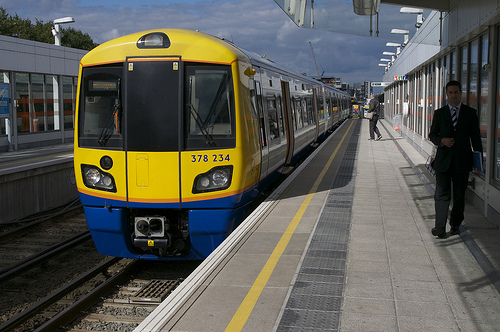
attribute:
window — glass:
[183, 66, 233, 138]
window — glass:
[90, 79, 122, 150]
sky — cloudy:
[80, 3, 274, 35]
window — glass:
[118, 67, 238, 134]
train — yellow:
[78, 30, 375, 278]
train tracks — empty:
[2, 194, 89, 289]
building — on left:
[3, 30, 88, 153]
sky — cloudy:
[75, 2, 280, 27]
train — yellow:
[81, 25, 258, 242]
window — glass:
[267, 56, 367, 171]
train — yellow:
[71, 23, 359, 263]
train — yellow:
[64, 56, 398, 287]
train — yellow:
[60, 15, 361, 283]